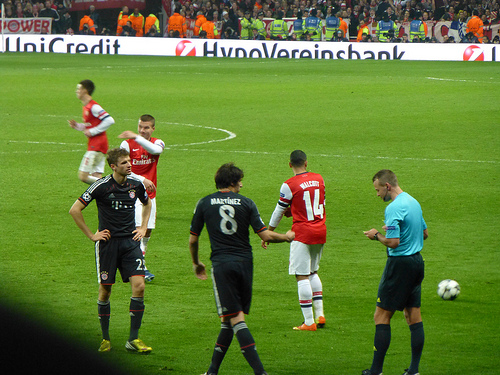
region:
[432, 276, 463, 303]
a white soccer ball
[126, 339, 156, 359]
yellow and white cleats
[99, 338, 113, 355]
yellow and white cleats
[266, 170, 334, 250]
a red and white jersey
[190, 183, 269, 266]
a blue and white jersey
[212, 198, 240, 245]
number 8 on a jersey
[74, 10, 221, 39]
people in orange jump suits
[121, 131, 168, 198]
a red and white jersey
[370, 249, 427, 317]
black soccer shorts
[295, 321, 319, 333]
orange and yellow cleats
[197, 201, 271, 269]
the number 8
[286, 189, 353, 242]
the number 14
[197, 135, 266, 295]
a man wearing a 8 jersey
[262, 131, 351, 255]
a man wearing a 14 jersey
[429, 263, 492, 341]
a soccer ball on the field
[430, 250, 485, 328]
a soccer ball on grass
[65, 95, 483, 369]
soccer players on the field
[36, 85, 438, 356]
men playing soccer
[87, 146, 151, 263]
a man wearing a jersey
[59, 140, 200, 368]
a man wearing yellow sneakers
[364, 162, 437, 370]
a ref with a blue shirt on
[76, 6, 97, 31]
a person wearing an orange jump suit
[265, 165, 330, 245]
a red and white soccer jersey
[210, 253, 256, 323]
blue soccer shorts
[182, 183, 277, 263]
a blue soccer jersey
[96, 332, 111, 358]
yellow and white cleats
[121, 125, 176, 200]
a red and white soccer jersey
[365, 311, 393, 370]
long blue socks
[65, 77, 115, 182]
Man with red and white jersey is running.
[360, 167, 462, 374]
Man with blue shirt is near soccer ball.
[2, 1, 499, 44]
Many people gathered to watch soccer game.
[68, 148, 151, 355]
Man with blonde hair is wearing black shirt.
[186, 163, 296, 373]
Man has number 8 on jersey.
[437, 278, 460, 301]
Soccer ball is black and white.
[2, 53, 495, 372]
Guys are gathered together to play soccer.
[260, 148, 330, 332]
Man with red shirt wearing orange shoes.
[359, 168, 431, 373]
Man with dark blue shorts is wearing knee high socks.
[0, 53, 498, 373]
White lines are painted on soccer field.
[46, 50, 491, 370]
men on a field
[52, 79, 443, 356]
men on a green field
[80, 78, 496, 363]
men on a green grass field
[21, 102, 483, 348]
men on a soccer field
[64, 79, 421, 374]
men that are playing soccer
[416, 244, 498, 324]
a ball on the field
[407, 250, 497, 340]
a ball on the grass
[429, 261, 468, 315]
a soccer ball on teh gras field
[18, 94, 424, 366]
men wearing uniforms